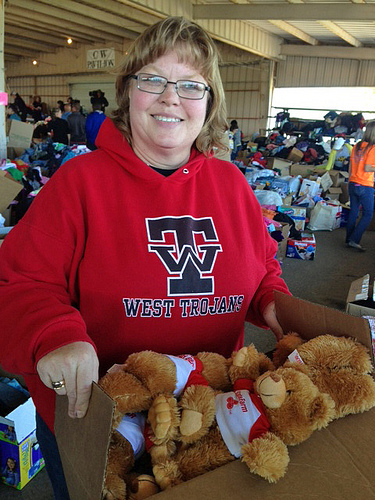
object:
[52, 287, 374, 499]
box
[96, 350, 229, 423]
teddy bears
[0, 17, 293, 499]
woman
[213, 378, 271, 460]
shirts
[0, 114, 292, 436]
sweatshirt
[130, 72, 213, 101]
glasses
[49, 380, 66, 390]
ring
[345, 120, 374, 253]
girl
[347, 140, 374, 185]
shirt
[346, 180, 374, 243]
jeans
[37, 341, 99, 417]
right hand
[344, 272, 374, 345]
box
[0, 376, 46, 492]
box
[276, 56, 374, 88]
door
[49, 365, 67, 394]
finger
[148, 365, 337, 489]
bear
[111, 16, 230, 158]
hair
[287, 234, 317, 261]
box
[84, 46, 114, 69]
sign